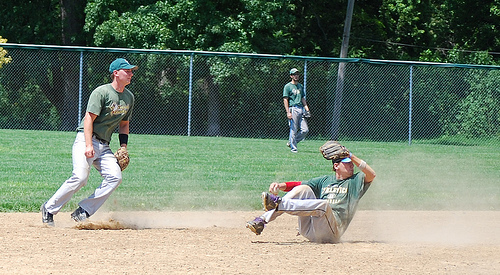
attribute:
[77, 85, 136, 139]
t shirt — green, t shirt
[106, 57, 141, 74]
cap — green, blue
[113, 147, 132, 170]
glove — tan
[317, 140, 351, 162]
glove — leather, brown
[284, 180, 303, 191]
sleeve — red, compression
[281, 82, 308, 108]
shirt — green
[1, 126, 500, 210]
grass — green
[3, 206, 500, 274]
ground — brown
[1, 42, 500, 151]
fence — metal, grey, green, wire, large, chain link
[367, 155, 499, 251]
cloud — dust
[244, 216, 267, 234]
cleats — black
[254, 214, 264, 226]
laces — purple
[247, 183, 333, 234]
legs — lifted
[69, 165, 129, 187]
knees — bent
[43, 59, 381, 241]
players — infield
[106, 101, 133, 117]
writing — yellow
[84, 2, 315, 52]
these — leaves, green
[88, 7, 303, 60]
leaves — green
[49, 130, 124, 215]
pants — white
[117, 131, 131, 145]
band — black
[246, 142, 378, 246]
man — slidding, sliding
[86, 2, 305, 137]
tree — large